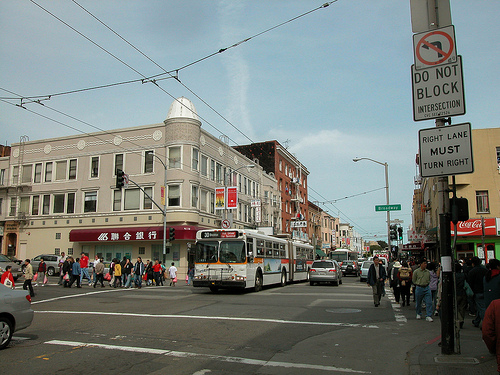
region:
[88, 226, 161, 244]
White chinese letters on red awning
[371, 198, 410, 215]
Green and white street sign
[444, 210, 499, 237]
Coca cola sign on building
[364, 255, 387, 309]
Man wearing white shirt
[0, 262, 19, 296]
Woman carrying white bag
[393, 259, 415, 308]
Person carrying a child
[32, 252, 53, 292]
Woman carrying pink bags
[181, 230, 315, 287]
White bus with orange and red stripe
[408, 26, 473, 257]
Three signs on black pole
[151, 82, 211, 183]
White dome on gray building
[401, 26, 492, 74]
a black and white sign for no left turns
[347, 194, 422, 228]
a green and white Broadway sign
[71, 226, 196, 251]
a maroon banner for storefront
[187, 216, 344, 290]
a white public transit bus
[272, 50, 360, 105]
clear blue skies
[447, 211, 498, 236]
red and white coca cola sign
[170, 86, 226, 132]
white dome on top of building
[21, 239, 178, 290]
a group of people crossing the street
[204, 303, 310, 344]
white lines on road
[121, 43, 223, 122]
electrical power lines across street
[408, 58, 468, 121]
do not block intersection sign is above the right lane must turn right sign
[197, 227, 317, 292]
bus driving through the intersection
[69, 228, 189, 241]
chinese lettering on a red awning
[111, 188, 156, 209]
apartment windows in building above stores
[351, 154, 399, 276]
street light on the corner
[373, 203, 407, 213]
green street sign attached to light post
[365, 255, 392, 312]
man crossing the street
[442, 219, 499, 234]
coca cola sign on building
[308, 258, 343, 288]
silver car driving down the street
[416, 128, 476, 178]
Right lane must turn right sign is posted to a pole at the intersection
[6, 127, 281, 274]
a large store on the corner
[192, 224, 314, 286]
a big bus in the road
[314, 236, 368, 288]
assorted cars next to the road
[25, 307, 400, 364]
the crosswalk in the street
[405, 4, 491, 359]
the street signs next to the road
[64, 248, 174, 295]
people crossing the road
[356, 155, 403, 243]
a street light with a sign on it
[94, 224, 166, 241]
a sign with asian writing on it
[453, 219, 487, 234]
the coca cola logo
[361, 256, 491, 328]
people crossing the street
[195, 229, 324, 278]
bus riding down the street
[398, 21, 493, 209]
signs on a pole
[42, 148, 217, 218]
large building with lots of windows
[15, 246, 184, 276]
people walking down the street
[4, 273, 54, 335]
silver car riding down the street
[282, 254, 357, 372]
silver car riding down the street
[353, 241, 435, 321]
people walking down the street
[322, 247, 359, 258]
bus driving down the street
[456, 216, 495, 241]
sign on a building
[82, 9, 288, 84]
power line over a street